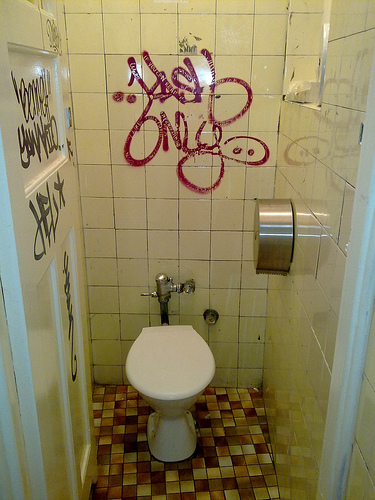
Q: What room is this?
A: It is a bathroom.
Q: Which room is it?
A: It is a bathroom.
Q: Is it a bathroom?
A: Yes, it is a bathroom.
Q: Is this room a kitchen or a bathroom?
A: It is a bathroom.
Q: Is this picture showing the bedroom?
A: No, the picture is showing the bathroom.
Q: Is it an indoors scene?
A: Yes, it is indoors.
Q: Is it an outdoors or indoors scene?
A: It is indoors.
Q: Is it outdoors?
A: No, it is indoors.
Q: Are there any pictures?
A: No, there are no pictures.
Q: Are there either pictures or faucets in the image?
A: No, there are no pictures or faucets.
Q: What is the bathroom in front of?
A: The bathroom is in front of the graffiti.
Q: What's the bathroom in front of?
A: The bathroom is in front of the graffiti.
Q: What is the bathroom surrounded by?
A: The bathroom is surrounded by the tiles.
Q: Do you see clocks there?
A: No, there are no clocks.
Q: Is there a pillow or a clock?
A: No, there are no clocks or pillows.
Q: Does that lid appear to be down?
A: Yes, the lid is down.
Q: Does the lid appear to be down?
A: Yes, the lid is down.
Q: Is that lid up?
A: No, the lid is down.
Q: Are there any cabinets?
A: No, there are no cabinets.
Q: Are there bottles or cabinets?
A: No, there are no cabinets or bottles.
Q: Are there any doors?
A: Yes, there is a door.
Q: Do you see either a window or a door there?
A: Yes, there is a door.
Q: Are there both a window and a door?
A: Yes, there are both a door and a window.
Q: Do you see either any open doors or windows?
A: Yes, there is an open door.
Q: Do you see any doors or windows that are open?
A: Yes, the door is open.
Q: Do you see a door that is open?
A: Yes, there is an open door.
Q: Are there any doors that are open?
A: Yes, there is a door that is open.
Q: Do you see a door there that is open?
A: Yes, there is a door that is open.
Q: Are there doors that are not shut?
A: Yes, there is a open door.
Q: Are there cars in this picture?
A: No, there are no cars.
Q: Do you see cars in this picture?
A: No, there are no cars.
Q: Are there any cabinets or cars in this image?
A: No, there are no cars or cabinets.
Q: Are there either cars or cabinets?
A: No, there are no cars or cabinets.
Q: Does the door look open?
A: Yes, the door is open.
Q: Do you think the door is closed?
A: No, the door is open.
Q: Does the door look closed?
A: No, the door is open.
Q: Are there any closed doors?
A: No, there is a door but it is open.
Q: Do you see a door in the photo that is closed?
A: No, there is a door but it is open.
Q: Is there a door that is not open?
A: No, there is a door but it is open.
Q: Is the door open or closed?
A: The door is open.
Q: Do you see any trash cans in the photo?
A: No, there are no trash cans.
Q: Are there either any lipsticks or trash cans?
A: No, there are no trash cans or lipsticks.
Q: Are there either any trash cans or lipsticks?
A: No, there are no trash cans or lipsticks.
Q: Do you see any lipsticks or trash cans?
A: No, there are no trash cans or lipsticks.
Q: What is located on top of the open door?
A: The graffiti is on top of the door.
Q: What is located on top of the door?
A: The graffiti is on top of the door.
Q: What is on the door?
A: The graffiti is on the door.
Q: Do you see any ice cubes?
A: No, there are no ice cubes.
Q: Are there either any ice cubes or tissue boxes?
A: No, there are no ice cubes or tissue boxes.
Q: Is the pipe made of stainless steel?
A: Yes, the pipe is made of stainless steel.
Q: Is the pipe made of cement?
A: No, the pipe is made of stainless steel.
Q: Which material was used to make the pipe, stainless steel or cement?
A: The pipe is made of stainless steel.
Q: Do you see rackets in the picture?
A: No, there are no rackets.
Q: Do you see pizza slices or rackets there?
A: No, there are no rackets or pizza slices.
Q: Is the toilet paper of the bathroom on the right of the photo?
A: Yes, the toilet paper is on the right of the image.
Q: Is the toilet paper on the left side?
A: No, the toilet paper is on the right of the image.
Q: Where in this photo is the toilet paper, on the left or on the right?
A: The toilet paper is on the right of the image.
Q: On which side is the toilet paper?
A: The toilet paper is on the right of the image.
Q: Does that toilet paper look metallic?
A: Yes, the toilet paper is metallic.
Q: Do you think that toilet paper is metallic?
A: Yes, the toilet paper is metallic.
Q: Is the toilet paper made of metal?
A: Yes, the toilet paper is made of metal.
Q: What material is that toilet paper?
A: The toilet paper is made of metal.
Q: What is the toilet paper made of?
A: The toilet paper is made of metal.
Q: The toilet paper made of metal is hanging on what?
A: The toilet paper is hanging on the bathroom.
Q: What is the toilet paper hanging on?
A: The toilet paper is hanging on the bathroom.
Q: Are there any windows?
A: Yes, there is a window.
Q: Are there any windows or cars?
A: Yes, there is a window.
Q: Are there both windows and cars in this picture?
A: No, there is a window but no cars.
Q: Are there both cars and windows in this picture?
A: No, there is a window but no cars.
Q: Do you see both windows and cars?
A: No, there is a window but no cars.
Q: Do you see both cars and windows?
A: No, there is a window but no cars.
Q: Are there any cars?
A: No, there are no cars.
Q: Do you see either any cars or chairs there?
A: No, there are no cars or chairs.